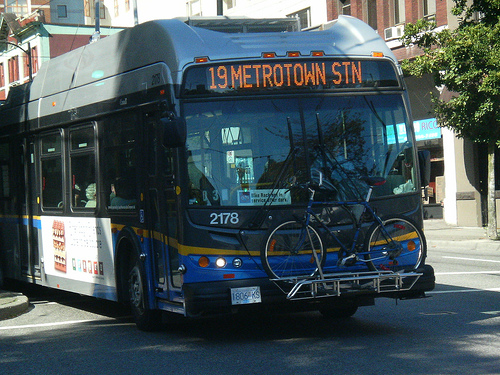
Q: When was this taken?
A: During the day.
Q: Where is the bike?
A: On the bus.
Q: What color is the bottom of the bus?
A: Blue.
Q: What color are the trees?
A: Green.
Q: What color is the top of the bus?
A: Gray.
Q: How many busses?
A: One.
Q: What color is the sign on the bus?
A: White.